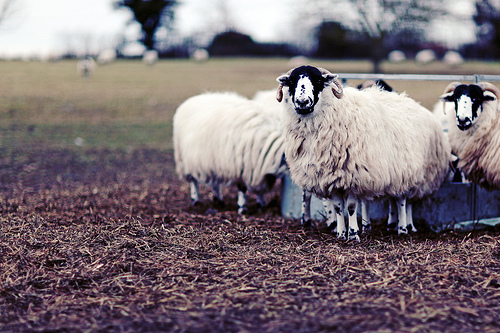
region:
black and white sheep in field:
[267, 65, 453, 240]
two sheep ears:
[272, 65, 343, 86]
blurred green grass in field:
[4, 55, 499, 147]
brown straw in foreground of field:
[0, 171, 498, 331]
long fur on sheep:
[302, 131, 372, 181]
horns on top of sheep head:
[316, 64, 349, 101]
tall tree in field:
[103, 0, 187, 62]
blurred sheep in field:
[387, 42, 469, 72]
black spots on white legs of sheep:
[291, 187, 313, 218]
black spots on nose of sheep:
[297, 82, 308, 97]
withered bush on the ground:
[53, 224, 220, 274]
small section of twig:
[341, 266, 399, 291]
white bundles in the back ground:
[384, 43, 461, 69]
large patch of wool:
[346, 112, 400, 144]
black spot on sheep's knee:
[343, 198, 370, 216]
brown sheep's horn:
[255, 73, 290, 104]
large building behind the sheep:
[185, 18, 298, 61]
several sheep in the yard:
[154, 45, 488, 216]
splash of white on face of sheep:
[292, 73, 319, 106]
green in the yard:
[33, 70, 148, 118]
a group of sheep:
[162, 57, 498, 232]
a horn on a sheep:
[320, 64, 340, 96]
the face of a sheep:
[280, 68, 330, 114]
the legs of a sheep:
[302, 190, 423, 237]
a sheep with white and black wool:
[285, 52, 453, 214]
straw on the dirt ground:
[105, 235, 281, 298]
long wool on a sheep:
[320, 130, 433, 182]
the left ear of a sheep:
[320, 73, 338, 85]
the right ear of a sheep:
[276, 72, 286, 84]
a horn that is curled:
[323, 67, 343, 101]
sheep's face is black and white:
[276, 57, 323, 129]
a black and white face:
[267, 56, 347, 123]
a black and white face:
[452, 73, 483, 146]